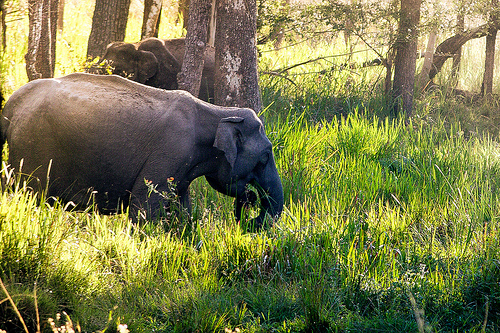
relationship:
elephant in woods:
[4, 72, 286, 240] [11, 10, 499, 240]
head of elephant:
[100, 35, 150, 91] [4, 45, 294, 270]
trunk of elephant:
[232, 180, 296, 233] [28, 50, 290, 272]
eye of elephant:
[256, 157, 269, 169] [4, 72, 286, 240]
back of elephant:
[50, 64, 186, 110] [4, 45, 294, 270]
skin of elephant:
[81, 122, 136, 148] [4, 72, 286, 240]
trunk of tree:
[210, 0, 262, 106] [208, 0, 268, 126]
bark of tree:
[384, 4, 425, 110] [396, 11, 420, 116]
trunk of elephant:
[232, 180, 296, 233] [4, 72, 286, 240]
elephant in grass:
[4, 72, 286, 240] [6, 64, 499, 326]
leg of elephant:
[124, 173, 167, 231] [4, 72, 286, 240]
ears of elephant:
[212, 113, 244, 173] [4, 72, 286, 240]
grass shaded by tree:
[6, 64, 499, 326] [333, 0, 499, 117]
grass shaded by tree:
[6, 64, 499, 326] [176, 0, 213, 102]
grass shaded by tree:
[6, 64, 499, 326] [83, 0, 133, 87]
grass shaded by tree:
[6, 64, 499, 326] [139, 1, 161, 46]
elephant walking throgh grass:
[4, 72, 286, 240] [0, 119, 495, 326]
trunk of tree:
[210, 5, 268, 127] [213, 3, 268, 122]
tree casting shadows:
[208, 0, 260, 109] [11, 223, 498, 330]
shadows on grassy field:
[11, 223, 498, 330] [1, 1, 498, 331]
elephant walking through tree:
[4, 72, 286, 240] [208, 0, 260, 109]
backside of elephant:
[1, 72, 61, 199] [4, 72, 286, 240]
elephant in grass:
[4, 72, 286, 240] [369, 135, 461, 200]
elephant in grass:
[4, 72, 286, 240] [333, 97, 389, 222]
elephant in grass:
[4, 72, 286, 240] [391, 229, 493, 322]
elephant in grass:
[88, 28, 195, 88] [223, 241, 371, 331]